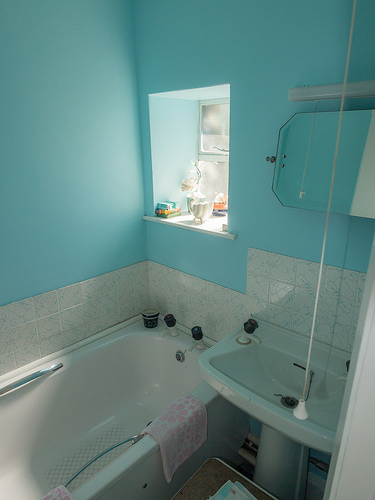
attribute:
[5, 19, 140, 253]
wall — blue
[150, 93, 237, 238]
window — bright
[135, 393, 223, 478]
towel — white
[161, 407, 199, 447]
flowers — pink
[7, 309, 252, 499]
bathtub — standard size, white, tiny, little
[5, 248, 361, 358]
tile — white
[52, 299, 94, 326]
swirls — blue marble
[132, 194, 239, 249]
shelving — built in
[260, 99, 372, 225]
mirror — eight sided, glass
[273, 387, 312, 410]
plug — sink drain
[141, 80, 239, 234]
window — small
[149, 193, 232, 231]
toys — bath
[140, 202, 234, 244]
sill — window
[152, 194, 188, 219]
train — little, toy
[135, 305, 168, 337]
candle — small, bathtub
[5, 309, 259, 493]
tub — white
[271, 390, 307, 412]
drain — light grey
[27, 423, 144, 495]
mat — white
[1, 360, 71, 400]
bar — silver, handicap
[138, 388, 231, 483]
towel — red, white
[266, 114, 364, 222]
cabinet — blue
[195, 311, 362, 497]
sink — little, white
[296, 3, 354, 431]
cord — white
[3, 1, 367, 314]
wall — light blue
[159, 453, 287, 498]
floor — light brown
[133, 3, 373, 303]
wall — blue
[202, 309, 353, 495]
sink — white, pedestal, bathroom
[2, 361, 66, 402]
handrail — silver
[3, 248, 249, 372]
wall — tile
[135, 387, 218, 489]
towel — pink, white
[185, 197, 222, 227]
bowl — white, glass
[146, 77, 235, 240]
hole — small, blue, window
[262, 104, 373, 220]
mirror — little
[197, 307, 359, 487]
sink — short, white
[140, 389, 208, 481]
towel — hanging , pink and white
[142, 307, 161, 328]
cup — black 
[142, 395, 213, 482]
towel — pink, white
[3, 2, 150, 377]
walls — blue, smooth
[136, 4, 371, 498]
walls — blue, smooth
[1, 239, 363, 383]
tiles — white, blue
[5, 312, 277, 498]
tub — white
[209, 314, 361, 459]
sink — white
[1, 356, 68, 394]
handle — silver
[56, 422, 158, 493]
handle — silver